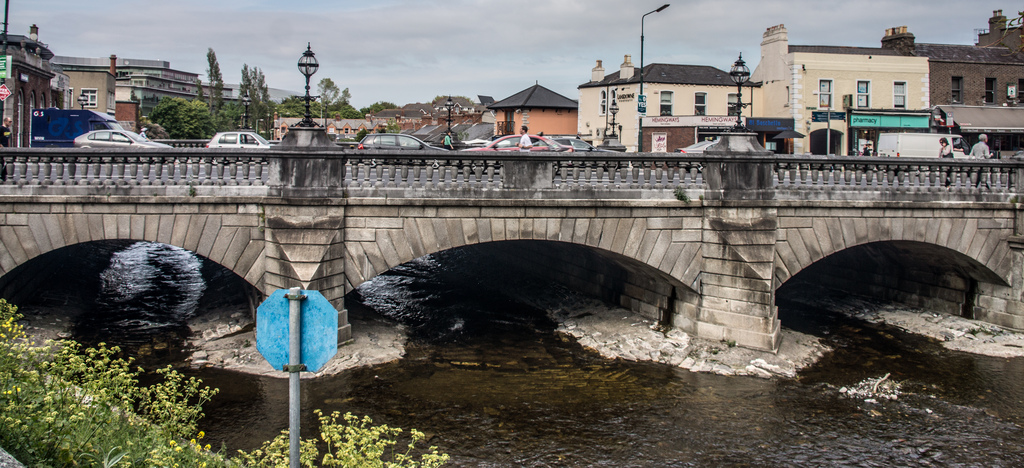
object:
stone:
[398, 206, 440, 218]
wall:
[493, 110, 578, 134]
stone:
[480, 206, 527, 219]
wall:
[639, 127, 697, 153]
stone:
[596, 207, 634, 219]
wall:
[577, 82, 642, 152]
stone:
[567, 207, 598, 219]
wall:
[641, 83, 765, 117]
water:
[487, 401, 818, 468]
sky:
[348, 0, 575, 81]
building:
[486, 78, 578, 139]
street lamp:
[635, 3, 669, 154]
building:
[751, 24, 931, 156]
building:
[878, 10, 1022, 156]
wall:
[927, 62, 1024, 105]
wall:
[801, 57, 929, 110]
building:
[0, 23, 56, 148]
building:
[639, 115, 748, 156]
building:
[745, 118, 795, 156]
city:
[0, 0, 1024, 468]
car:
[69, 128, 174, 150]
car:
[201, 130, 274, 149]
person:
[511, 124, 540, 152]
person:
[966, 131, 996, 160]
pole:
[281, 286, 310, 468]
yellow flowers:
[0, 316, 29, 332]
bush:
[228, 410, 452, 468]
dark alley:
[343, 237, 704, 345]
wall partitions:
[501, 219, 510, 240]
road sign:
[252, 284, 339, 380]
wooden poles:
[397, 160, 411, 190]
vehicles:
[462, 133, 575, 151]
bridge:
[0, 42, 1022, 381]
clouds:
[362, 18, 535, 68]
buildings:
[933, 104, 1024, 159]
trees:
[199, 46, 227, 138]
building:
[576, 54, 760, 150]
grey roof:
[480, 79, 578, 111]